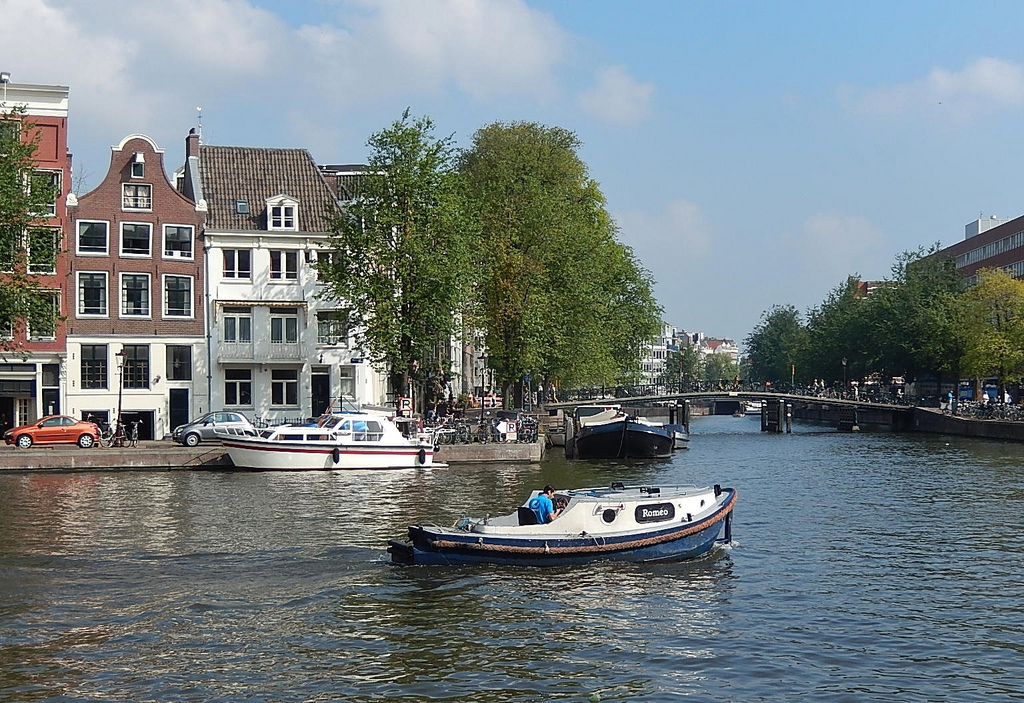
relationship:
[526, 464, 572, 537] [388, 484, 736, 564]
man driving boat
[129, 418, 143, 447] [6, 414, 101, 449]
bicycle in front of car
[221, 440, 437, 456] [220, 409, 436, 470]
stripe on boat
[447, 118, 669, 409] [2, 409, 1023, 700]
trees along water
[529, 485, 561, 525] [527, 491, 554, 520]
man wearing shirt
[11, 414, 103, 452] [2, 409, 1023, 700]
car near water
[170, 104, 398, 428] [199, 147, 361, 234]
building with roof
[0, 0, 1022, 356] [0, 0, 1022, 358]
clouds in sky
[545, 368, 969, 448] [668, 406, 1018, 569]
bridge over water way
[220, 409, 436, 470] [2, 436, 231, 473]
boat parked by street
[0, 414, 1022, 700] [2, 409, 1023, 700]
ripples are on water